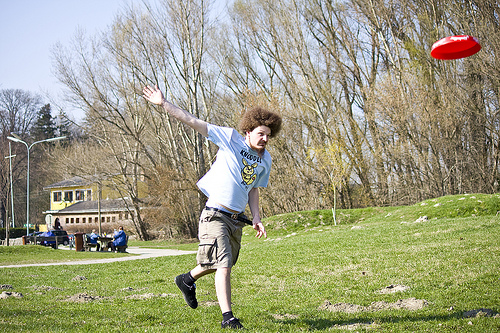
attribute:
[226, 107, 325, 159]
hair — curly, brown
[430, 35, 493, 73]
frisbee — flying, red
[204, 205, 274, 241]
belt — black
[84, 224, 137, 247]
people — sitting, sitting.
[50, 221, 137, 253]
cars — parked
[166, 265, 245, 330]
shoes — black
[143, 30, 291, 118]
trees — bare